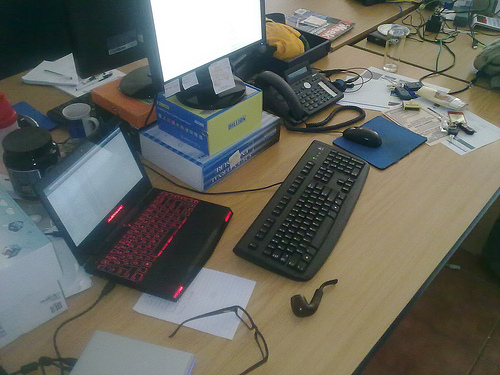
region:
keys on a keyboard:
[95, 191, 202, 286]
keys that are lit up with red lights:
[98, 189, 199, 286]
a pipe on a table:
[291, 278, 338, 318]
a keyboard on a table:
[233, 139, 372, 283]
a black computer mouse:
[344, 124, 381, 150]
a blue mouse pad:
[334, 114, 427, 171]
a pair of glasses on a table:
[170, 302, 272, 374]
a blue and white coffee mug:
[63, 102, 98, 140]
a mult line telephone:
[257, 66, 366, 130]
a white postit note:
[207, 57, 237, 97]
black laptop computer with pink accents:
[34, 118, 231, 302]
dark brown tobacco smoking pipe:
[291, 278, 337, 318]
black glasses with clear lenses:
[166, 303, 268, 373]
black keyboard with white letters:
[230, 138, 371, 281]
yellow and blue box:
[156, 81, 262, 154]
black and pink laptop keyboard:
[93, 188, 200, 284]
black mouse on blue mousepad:
[337, 114, 427, 170]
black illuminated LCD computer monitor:
[145, 0, 263, 92]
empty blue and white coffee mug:
[63, 101, 98, 140]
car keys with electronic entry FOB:
[436, 117, 475, 144]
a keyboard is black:
[235, 139, 370, 286]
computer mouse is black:
[342, 125, 384, 147]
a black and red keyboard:
[30, 117, 232, 302]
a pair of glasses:
[172, 304, 269, 374]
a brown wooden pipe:
[290, 277, 338, 314]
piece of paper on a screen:
[207, 57, 235, 94]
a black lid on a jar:
[2, 127, 58, 199]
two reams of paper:
[0, 188, 68, 345]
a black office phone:
[259, 60, 342, 128]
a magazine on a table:
[285, 9, 354, 42]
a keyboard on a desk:
[235, 136, 376, 283]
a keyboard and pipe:
[239, 139, 369, 319]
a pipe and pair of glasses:
[162, 280, 349, 369]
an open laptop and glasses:
[37, 121, 272, 371]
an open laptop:
[34, 117, 234, 307]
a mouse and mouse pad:
[327, 108, 427, 168]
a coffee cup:
[57, 93, 103, 146]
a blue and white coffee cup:
[57, 93, 104, 143]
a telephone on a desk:
[252, 59, 347, 133]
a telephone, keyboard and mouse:
[257, 63, 387, 284]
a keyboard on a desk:
[230, 138, 365, 284]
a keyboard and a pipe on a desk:
[235, 133, 372, 320]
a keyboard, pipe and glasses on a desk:
[178, 138, 373, 368]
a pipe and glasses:
[175, 275, 362, 365]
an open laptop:
[30, 115, 235, 305]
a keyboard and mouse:
[240, 116, 387, 281]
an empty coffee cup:
[57, 96, 102, 143]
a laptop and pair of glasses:
[32, 125, 268, 371]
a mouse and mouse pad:
[333, 110, 427, 158]